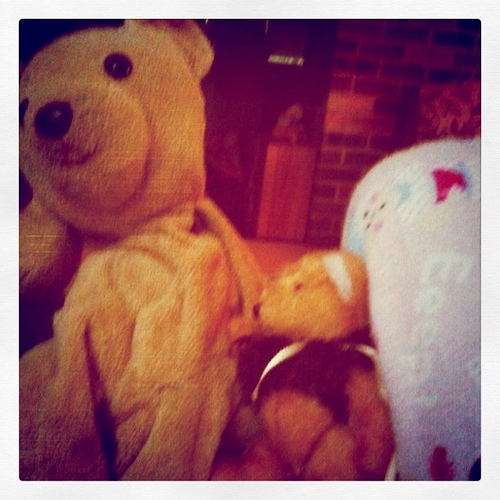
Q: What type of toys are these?
A: Teddy bears.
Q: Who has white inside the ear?
A: Middle bear.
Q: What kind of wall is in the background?
A: Brick.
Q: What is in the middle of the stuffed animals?
A: Small brown teddy bear.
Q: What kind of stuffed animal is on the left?
A: Large brown bear.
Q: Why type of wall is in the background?
A: Brick.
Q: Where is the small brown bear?
A: In the middle.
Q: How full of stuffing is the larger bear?
A: Slightly.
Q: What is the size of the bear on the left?
A: Large.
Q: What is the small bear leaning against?
A: White blanket.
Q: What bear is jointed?
A: One in the middle.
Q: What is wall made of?
A: Brick.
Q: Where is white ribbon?
A: Small bear.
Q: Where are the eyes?
A: Bear.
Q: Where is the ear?
A: On bear.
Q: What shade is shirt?
A: Dark.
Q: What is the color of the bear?
A: Brown.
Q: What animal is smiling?
A: Bear.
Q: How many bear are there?
A: Two.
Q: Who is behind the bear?
A: No one.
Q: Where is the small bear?
A: Beside the big bear.